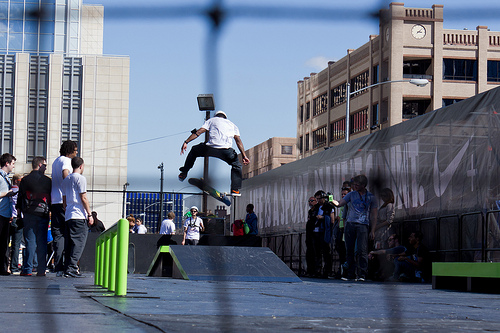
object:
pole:
[88, 211, 106, 233]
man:
[177, 110, 250, 196]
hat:
[213, 110, 229, 119]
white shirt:
[198, 117, 241, 149]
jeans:
[179, 142, 242, 189]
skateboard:
[186, 177, 234, 206]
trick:
[178, 110, 250, 207]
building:
[0, 0, 131, 232]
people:
[60, 156, 95, 278]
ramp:
[145, 244, 304, 281]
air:
[146, 25, 312, 60]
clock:
[410, 24, 426, 40]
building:
[294, 2, 498, 160]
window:
[23, 2, 41, 20]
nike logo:
[432, 132, 476, 198]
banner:
[231, 87, 499, 283]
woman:
[373, 188, 395, 280]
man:
[386, 231, 433, 283]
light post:
[157, 161, 165, 235]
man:
[15, 155, 53, 275]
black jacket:
[15, 170, 53, 220]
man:
[242, 203, 260, 236]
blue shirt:
[245, 211, 259, 236]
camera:
[321, 192, 333, 204]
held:
[320, 191, 352, 208]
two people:
[303, 189, 336, 279]